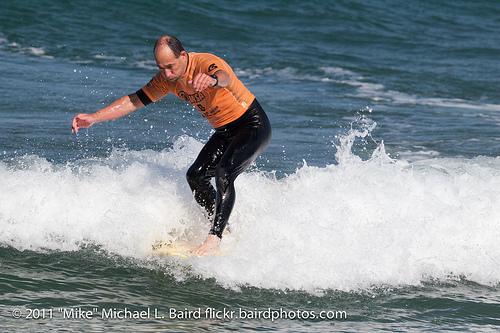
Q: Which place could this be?
A: It is an ocean.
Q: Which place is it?
A: It is an ocean.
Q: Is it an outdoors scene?
A: Yes, it is outdoors.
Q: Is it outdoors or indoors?
A: It is outdoors.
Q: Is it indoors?
A: No, it is outdoors.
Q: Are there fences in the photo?
A: No, there are no fences.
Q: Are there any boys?
A: No, there are no boys.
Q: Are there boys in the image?
A: No, there are no boys.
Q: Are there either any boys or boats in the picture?
A: No, there are no boys or boats.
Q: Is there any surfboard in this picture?
A: Yes, there is a surfboard.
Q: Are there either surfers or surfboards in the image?
A: Yes, there is a surfboard.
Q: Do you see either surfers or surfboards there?
A: Yes, there is a surfboard.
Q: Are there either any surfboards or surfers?
A: Yes, there is a surfboard.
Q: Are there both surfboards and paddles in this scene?
A: No, there is a surfboard but no paddles.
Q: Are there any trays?
A: No, there are no trays.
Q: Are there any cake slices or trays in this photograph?
A: No, there are no trays or cake slices.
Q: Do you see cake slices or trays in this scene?
A: No, there are no trays or cake slices.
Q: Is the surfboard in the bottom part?
A: Yes, the surfboard is in the bottom of the image.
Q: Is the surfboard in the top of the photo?
A: No, the surfboard is in the bottom of the image.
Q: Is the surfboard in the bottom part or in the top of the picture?
A: The surfboard is in the bottom of the image.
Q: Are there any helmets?
A: No, there are no helmets.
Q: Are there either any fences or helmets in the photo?
A: No, there are no helmets or fences.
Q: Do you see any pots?
A: No, there are no pots.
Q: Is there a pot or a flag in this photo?
A: No, there are no pots or flags.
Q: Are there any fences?
A: No, there are no fences.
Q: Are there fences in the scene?
A: No, there are no fences.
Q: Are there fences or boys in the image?
A: No, there are no fences or boys.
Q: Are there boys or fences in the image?
A: No, there are no fences or boys.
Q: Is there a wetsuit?
A: Yes, there is a wetsuit.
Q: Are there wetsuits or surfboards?
A: Yes, there is a wetsuit.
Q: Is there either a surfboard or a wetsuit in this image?
A: Yes, there is a wetsuit.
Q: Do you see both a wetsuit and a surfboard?
A: Yes, there are both a wetsuit and a surfboard.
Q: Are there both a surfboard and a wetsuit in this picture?
A: Yes, there are both a wetsuit and a surfboard.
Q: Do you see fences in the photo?
A: No, there are no fences.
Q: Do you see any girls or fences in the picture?
A: No, there are no fences or girls.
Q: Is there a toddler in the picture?
A: No, there are no toddlers.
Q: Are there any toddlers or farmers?
A: No, there are no toddlers or farmers.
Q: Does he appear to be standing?
A: Yes, the man is standing.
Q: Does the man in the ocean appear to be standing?
A: Yes, the man is standing.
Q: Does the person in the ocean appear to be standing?
A: Yes, the man is standing.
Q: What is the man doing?
A: The man is standing.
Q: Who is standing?
A: The man is standing.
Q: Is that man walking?
A: No, the man is standing.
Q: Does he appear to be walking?
A: No, the man is standing.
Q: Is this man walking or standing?
A: The man is standing.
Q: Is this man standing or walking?
A: The man is standing.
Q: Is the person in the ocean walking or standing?
A: The man is standing.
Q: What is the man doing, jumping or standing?
A: The man is standing.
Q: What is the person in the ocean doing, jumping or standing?
A: The man is standing.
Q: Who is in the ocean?
A: The man is in the ocean.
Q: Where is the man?
A: The man is in the ocean.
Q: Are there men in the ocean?
A: Yes, there is a man in the ocean.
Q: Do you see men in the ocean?
A: Yes, there is a man in the ocean.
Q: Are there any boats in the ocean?
A: No, there is a man in the ocean.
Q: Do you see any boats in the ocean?
A: No, there is a man in the ocean.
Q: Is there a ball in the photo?
A: No, there are no balls.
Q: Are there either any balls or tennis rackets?
A: No, there are no balls or tennis rackets.